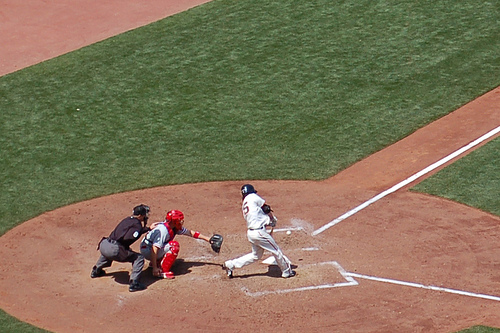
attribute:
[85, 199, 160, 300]
umpire — calling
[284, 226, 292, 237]
ball — white, airborne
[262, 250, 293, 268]
plate — home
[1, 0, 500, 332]
grass — green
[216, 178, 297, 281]
batter — right handed, hitting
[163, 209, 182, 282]
gear — red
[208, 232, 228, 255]
mitt — catcher's, black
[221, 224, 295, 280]
pants — white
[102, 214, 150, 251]
shirt — black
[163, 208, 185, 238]
helmet — red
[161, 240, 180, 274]
guards — red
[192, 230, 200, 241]
band — red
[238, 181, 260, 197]
helmet — black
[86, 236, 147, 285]
pants — gray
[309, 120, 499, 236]
line — white